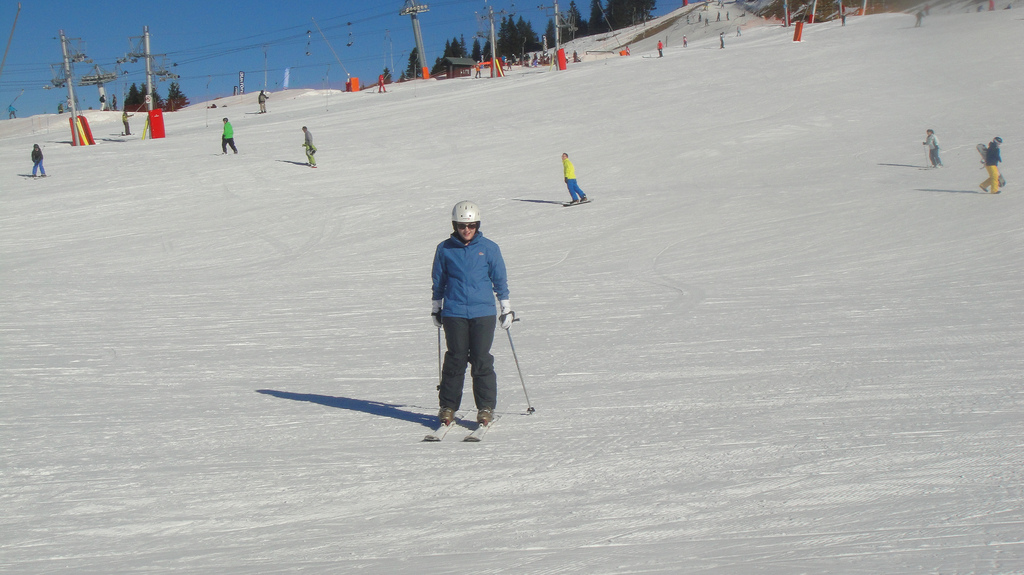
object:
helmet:
[452, 200, 481, 231]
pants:
[980, 165, 1000, 193]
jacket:
[562, 158, 576, 179]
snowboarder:
[221, 117, 238, 154]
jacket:
[222, 122, 233, 138]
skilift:
[0, 0, 555, 117]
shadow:
[255, 388, 480, 431]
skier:
[430, 200, 537, 443]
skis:
[424, 414, 501, 442]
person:
[431, 200, 514, 426]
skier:
[923, 129, 943, 169]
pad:
[69, 115, 96, 146]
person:
[31, 144, 47, 178]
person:
[122, 109, 134, 135]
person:
[222, 117, 238, 154]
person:
[977, 136, 1006, 194]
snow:
[0, 222, 385, 367]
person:
[923, 129, 943, 169]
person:
[302, 125, 318, 168]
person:
[561, 152, 592, 206]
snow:
[0, 0, 1024, 574]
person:
[378, 74, 386, 92]